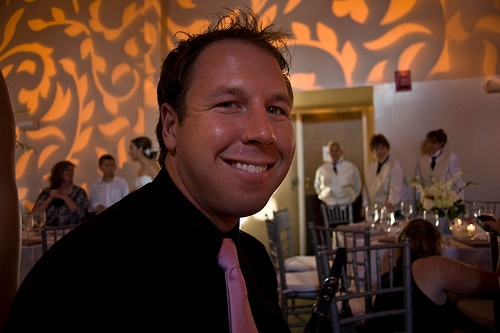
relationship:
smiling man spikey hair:
[0, 6, 296, 331] [156, 7, 292, 169]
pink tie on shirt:
[216, 237, 260, 332] [7, 168, 291, 332]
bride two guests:
[128, 138, 162, 190] [30, 154, 129, 225]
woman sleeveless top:
[128, 138, 162, 190] [134, 174, 154, 189]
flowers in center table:
[409, 170, 472, 211] [328, 219, 499, 286]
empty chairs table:
[265, 202, 414, 332] [328, 219, 499, 286]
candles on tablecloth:
[450, 218, 478, 238] [328, 219, 499, 286]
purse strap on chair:
[306, 247, 353, 332] [315, 244, 415, 331]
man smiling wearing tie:
[0, 6, 296, 331] [216, 237, 260, 332]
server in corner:
[413, 129, 461, 193] [462, 139, 499, 189]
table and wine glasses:
[328, 219, 499, 286] [364, 199, 442, 229]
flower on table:
[409, 170, 472, 211] [328, 219, 499, 286]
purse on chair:
[306, 247, 353, 332] [315, 244, 415, 331]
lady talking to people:
[128, 138, 162, 190] [30, 154, 129, 225]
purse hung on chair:
[306, 247, 353, 332] [315, 244, 415, 331]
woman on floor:
[368, 219, 499, 331] [280, 298, 498, 332]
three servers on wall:
[313, 129, 466, 208] [375, 78, 499, 206]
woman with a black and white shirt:
[368, 219, 499, 331] [31, 184, 89, 225]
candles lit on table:
[450, 218, 478, 238] [328, 219, 499, 286]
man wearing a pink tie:
[0, 6, 296, 331] [216, 237, 260, 332]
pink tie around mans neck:
[216, 237, 260, 332] [159, 154, 240, 236]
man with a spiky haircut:
[0, 6, 296, 331] [156, 7, 292, 169]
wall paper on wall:
[0, 0, 499, 224] [375, 78, 499, 206]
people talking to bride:
[30, 154, 129, 225] [128, 138, 162, 190]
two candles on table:
[266, 209, 319, 327] [328, 219, 499, 286]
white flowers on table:
[409, 170, 472, 211] [328, 219, 499, 286]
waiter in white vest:
[314, 139, 362, 210] [319, 164, 354, 211]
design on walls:
[13, 41, 59, 114] [2, 3, 149, 158]